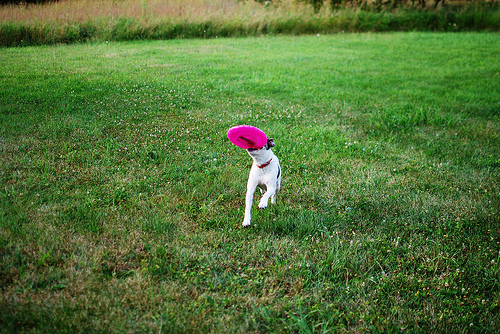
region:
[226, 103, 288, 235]
the dog is catching a frisbee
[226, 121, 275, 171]
the frisbee is pink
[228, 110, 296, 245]
the dog is black & white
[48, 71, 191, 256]
the grass has a lot of clover in it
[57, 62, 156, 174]
the grass is a beautiful shade of green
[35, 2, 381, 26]
the background is full of weeds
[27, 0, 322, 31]
the weeds are brown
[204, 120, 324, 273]
the dog has all four feet off the ground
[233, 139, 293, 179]
he is wearing a red collar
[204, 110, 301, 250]
the dog is the focus of the photo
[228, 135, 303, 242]
dog is wearing a collar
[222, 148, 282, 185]
dog is wearing a collar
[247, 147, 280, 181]
dog is wearing a collar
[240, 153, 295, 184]
dog is wearing a collar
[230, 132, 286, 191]
the collar is red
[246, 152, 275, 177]
the collar is red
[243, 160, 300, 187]
the collar is red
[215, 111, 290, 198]
the frisbee is pink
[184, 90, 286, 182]
the frisbee is pink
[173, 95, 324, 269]
frisbee caught by the dog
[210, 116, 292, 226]
frisbee caught by the dog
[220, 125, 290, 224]
a dog running with a frisbee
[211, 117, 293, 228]
a dog with a pink frisbee in it's mouth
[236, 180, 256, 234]
the leg of a dog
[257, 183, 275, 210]
the leg of a dog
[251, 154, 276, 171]
the collar around a dogs neck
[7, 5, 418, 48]
the tall grass at the edge of a lawn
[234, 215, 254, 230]
a paw of a dog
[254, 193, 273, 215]
a paw of a dog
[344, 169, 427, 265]
the green grass of a lawn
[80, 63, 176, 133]
the green grass of a lawn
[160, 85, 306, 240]
dog playing with frisbee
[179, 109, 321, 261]
dog carrying pink frisbee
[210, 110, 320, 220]
white dog running with frisbee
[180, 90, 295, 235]
small white dog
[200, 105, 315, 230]
small white dog wearing a red collar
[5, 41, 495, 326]
field of grass dog is playing in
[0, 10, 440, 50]
bushes around property line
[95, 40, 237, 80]
multiple bald spots in grass field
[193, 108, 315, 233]
dog with upside down frisbee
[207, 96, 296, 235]
small dog running